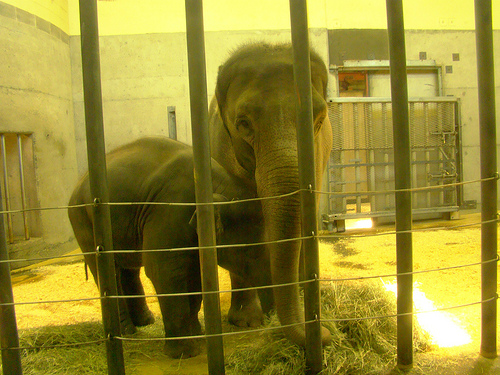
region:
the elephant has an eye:
[229, 100, 265, 142]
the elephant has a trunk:
[252, 154, 304, 347]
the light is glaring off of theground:
[385, 267, 472, 353]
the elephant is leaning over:
[44, 140, 241, 363]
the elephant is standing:
[185, 32, 342, 368]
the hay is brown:
[339, 295, 381, 364]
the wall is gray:
[8, 42, 68, 94]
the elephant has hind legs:
[80, 244, 156, 342]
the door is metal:
[417, 85, 469, 223]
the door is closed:
[337, 95, 472, 227]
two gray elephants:
[68, 40, 333, 352]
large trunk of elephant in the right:
[247, 129, 331, 353]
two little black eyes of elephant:
[233, 109, 329, 139]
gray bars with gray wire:
[0, 0, 499, 372]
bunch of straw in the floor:
[0, 265, 426, 373]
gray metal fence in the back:
[302, 94, 464, 229]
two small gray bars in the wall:
[0, 129, 36, 259]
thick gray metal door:
[334, 60, 445, 225]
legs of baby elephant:
[75, 230, 214, 353]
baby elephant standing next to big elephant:
[66, 139, 286, 359]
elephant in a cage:
[228, 36, 355, 342]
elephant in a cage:
[50, 127, 236, 365]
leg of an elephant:
[145, 221, 203, 366]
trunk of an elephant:
[251, 145, 313, 345]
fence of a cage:
[305, 171, 435, 366]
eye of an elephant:
[225, 97, 270, 157]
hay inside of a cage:
[345, 325, 395, 370]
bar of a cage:
[388, 16, 439, 371]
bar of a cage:
[290, 21, 335, 372]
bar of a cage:
[179, 30, 232, 372]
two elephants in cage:
[108, 53, 327, 322]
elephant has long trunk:
[252, 152, 324, 345]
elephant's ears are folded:
[207, 57, 332, 138]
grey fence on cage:
[332, 82, 483, 199]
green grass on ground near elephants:
[276, 274, 478, 370]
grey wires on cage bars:
[9, 178, 494, 335]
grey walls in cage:
[136, 30, 196, 150]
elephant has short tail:
[73, 235, 96, 297]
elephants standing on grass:
[96, 306, 295, 373]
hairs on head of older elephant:
[216, 27, 318, 88]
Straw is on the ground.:
[235, 269, 477, 374]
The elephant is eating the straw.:
[207, 40, 347, 342]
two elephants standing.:
[67, 51, 374, 355]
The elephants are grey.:
[57, 41, 345, 337]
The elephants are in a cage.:
[15, 5, 499, 332]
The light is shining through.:
[372, 265, 465, 369]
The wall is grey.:
[5, 3, 485, 228]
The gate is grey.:
[324, 94, 464, 220]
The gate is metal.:
[329, 94, 468, 221]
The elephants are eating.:
[62, 37, 356, 347]